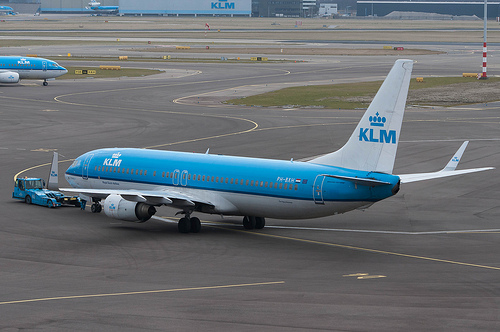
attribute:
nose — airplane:
[62, 150, 82, 183]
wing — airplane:
[52, 175, 160, 202]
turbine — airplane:
[93, 188, 168, 220]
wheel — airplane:
[170, 213, 283, 237]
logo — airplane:
[357, 109, 409, 153]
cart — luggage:
[0, 169, 73, 209]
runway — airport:
[58, 232, 498, 330]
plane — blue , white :
[44, 74, 414, 248]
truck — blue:
[13, 167, 59, 207]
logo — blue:
[358, 110, 393, 128]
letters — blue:
[351, 122, 402, 149]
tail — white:
[335, 55, 431, 164]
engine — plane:
[92, 193, 161, 223]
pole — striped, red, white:
[475, 30, 498, 100]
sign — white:
[114, 0, 256, 15]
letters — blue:
[201, 0, 236, 16]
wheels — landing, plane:
[84, 197, 114, 224]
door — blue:
[297, 167, 332, 209]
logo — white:
[100, 148, 120, 158]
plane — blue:
[30, 74, 416, 229]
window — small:
[186, 167, 201, 185]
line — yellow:
[260, 224, 499, 297]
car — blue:
[14, 163, 59, 206]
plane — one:
[28, 60, 448, 230]